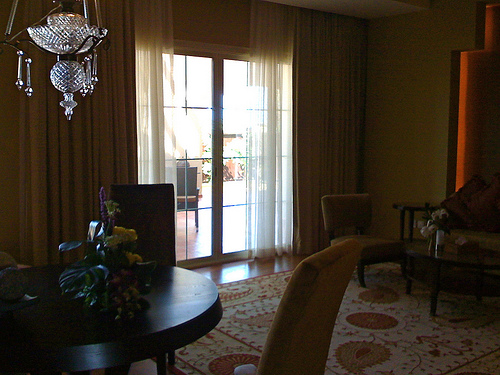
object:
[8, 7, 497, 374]
living area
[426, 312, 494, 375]
rug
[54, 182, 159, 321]
arrangement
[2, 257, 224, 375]
table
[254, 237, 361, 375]
chair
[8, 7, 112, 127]
chandelier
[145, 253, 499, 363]
floor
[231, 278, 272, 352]
carpet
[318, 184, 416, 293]
chair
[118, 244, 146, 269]
flowers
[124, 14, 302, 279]
curtains